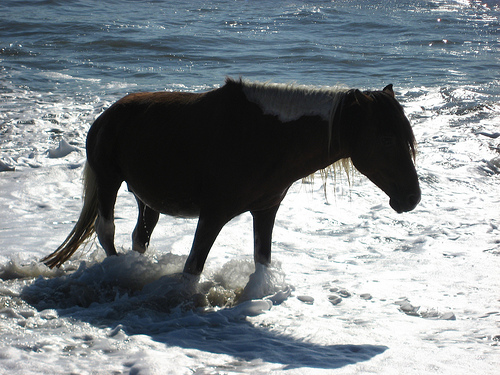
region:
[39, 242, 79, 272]
Part of the horse's tail.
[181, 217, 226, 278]
The front leg of the horse.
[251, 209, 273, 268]
The horse's front leg.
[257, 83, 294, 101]
Part of the horse's mane.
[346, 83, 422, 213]
The head of the horse.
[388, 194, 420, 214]
The horse's mouth.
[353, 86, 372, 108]
The ear of the horse.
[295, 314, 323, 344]
Part of the foamy water.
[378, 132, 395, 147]
The eye of the horse.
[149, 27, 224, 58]
Part of the water.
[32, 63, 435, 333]
horse walking in water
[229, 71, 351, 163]
horse mane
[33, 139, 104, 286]
horse tail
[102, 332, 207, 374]
white froth on top of water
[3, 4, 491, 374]
body of water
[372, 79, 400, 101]
ear on horse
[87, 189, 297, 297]
four horse legs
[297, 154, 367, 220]
wet horse hair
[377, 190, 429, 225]
silhouette of horse mouth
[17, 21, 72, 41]
wet horse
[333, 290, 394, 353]
waves in white and blue ocean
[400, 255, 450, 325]
waves in white and blue ocean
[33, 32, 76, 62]
waves in white and blue ocean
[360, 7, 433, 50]
waves in white and blue ocean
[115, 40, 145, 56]
waves in white and blue ocean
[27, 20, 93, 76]
waves in white and blue ocean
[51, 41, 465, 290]
the horse is wet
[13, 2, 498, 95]
the ocean is calm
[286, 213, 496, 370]
the water is foamy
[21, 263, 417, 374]
shadow of the horse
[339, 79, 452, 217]
the head of the horse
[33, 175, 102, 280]
the tail of the horse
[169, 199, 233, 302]
leg of the horse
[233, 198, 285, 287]
leg of the horse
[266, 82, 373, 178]
the neck of the horse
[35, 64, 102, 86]
white foam in sea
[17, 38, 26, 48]
white foam in sea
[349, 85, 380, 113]
Ear of a horse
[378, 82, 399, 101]
Ear of a horse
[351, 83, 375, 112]
Ear of a brown horse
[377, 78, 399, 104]
Ear of a brown horse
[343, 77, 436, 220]
Head of a horse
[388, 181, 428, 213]
Nose of a horse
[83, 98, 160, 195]
Rear of a horse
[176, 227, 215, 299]
Leg of a horse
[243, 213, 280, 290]
Leg of a horse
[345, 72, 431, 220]
Head of a horse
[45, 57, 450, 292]
horse in the water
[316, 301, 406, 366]
shadow of the horse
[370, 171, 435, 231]
nose of the horse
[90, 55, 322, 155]
back of the horse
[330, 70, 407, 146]
hair on the horse's head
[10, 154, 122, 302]
tail of the horse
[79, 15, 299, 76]
ripples in the water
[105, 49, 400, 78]
water near the horse